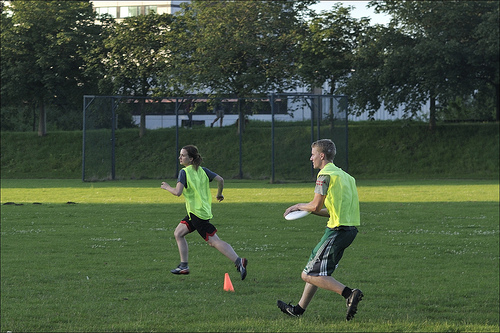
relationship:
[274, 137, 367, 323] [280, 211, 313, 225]
man holding frisbee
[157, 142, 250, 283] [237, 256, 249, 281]
woman has foot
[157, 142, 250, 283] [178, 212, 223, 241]
woman wearing shorts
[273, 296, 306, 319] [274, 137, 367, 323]
cleat worn by man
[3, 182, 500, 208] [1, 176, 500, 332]
sunlight on field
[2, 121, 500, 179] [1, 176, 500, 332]
hill surrounding field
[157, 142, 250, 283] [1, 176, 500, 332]
woman running on field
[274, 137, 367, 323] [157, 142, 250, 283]
man running behind woman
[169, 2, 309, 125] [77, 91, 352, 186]
tree near goal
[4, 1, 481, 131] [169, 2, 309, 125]
building near tree